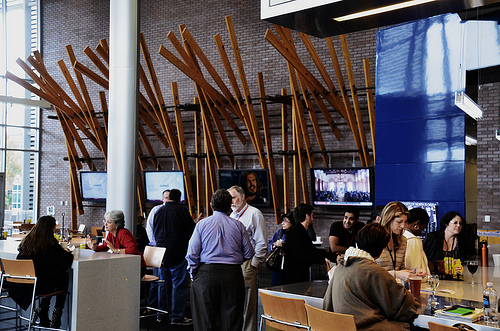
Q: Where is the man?
A: By a table.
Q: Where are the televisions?
A: On the wall.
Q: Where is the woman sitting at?
A: The table.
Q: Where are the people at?
A: The restaurant.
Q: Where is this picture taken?
A: A restaurant.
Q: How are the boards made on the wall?
A: Of wood.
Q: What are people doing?
A: Dining.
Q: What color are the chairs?
A: Oak.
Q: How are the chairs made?
A: Of wood and metal.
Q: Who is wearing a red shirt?
A: Woman left table.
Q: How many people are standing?
A: 4.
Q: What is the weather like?
A: Sunny.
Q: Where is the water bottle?
A: Bottom right corner table.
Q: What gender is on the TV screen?
A: Male.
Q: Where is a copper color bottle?
A: Right side next to lady black shirt.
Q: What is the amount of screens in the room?
A: 4.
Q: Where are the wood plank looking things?
A: Behind tvs.